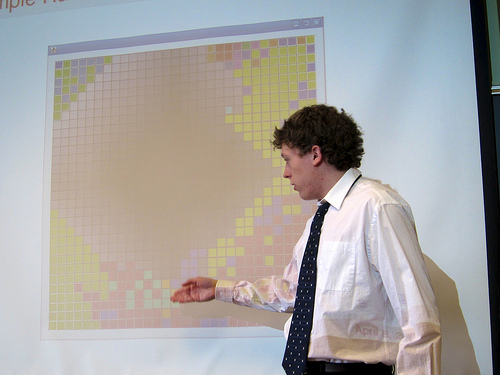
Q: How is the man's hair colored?
A: Brown.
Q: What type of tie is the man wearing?
A: A necktie.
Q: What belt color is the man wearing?
A: Black belt.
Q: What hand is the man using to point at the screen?
A: Right hand.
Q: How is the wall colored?
A: White.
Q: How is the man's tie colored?
A: Dark blue.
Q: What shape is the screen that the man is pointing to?
A: Square.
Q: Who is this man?
A: A teacher.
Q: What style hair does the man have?
A: Short.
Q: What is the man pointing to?
A: A colorful graph.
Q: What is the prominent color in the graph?
A: Peach.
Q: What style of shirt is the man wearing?
A: Dress shirt.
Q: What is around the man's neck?
A: A tie.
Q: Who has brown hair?
A: The man.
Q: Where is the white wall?
A: Behind the man.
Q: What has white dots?
A: The tie.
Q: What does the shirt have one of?
A: Pockets.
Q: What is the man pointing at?
A: Pixels on a board.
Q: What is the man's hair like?
A: Messy.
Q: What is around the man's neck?
A: Tie.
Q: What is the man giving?
A: A presentation.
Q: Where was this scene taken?
A: Classroom.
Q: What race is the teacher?
A: Caucasian.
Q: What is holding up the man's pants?
A: Black belt.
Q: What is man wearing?
A: White shirt.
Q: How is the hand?
A: Stretched.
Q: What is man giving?
A: Presentation.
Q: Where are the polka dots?
A: Tie.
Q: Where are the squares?
A: On picture.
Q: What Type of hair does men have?
A: Curly.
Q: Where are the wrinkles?
A: On shirt.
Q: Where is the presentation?
A: On screen.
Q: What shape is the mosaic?
A: Square.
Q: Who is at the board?
A: A man.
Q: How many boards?
A: 1.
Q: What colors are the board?
A: Yellow, white, blue, and green.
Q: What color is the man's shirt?
A: White.